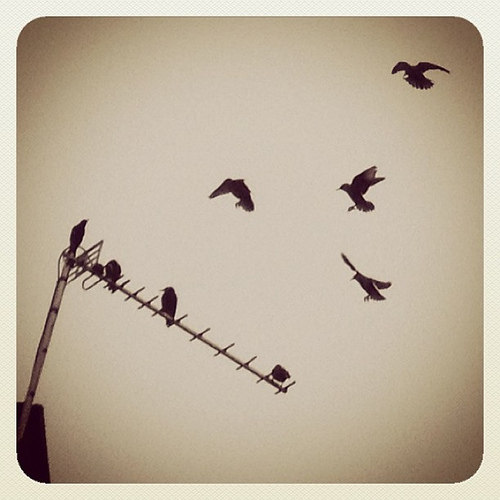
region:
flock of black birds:
[79, 47, 463, 407]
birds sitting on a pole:
[72, 203, 292, 360]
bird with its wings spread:
[323, 242, 405, 332]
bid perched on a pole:
[38, 200, 116, 261]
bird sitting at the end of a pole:
[261, 354, 327, 427]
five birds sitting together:
[56, 208, 308, 392]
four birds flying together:
[211, 52, 469, 303]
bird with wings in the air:
[327, 147, 396, 224]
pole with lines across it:
[61, 211, 319, 405]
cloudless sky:
[61, 67, 431, 446]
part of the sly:
[130, 123, 180, 188]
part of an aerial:
[212, 335, 244, 406]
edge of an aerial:
[271, 367, 293, 402]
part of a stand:
[17, 332, 64, 392]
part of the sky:
[366, 326, 427, 400]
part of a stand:
[23, 343, 63, 426]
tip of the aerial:
[283, 380, 298, 390]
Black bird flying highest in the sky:
[385, 55, 455, 90]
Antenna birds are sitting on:
[55, 245, 296, 400]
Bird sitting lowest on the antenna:
[265, 360, 290, 385]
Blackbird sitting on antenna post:
[61, 211, 91, 256]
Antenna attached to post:
[16, 242, 73, 457]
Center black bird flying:
[205, 172, 260, 212]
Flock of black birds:
[65, 55, 470, 385]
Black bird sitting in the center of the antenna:
[155, 275, 185, 330]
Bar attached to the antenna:
[185, 325, 210, 340]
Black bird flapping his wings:
[336, 160, 396, 218]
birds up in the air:
[29, 37, 450, 476]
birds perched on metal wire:
[64, 237, 304, 421]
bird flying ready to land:
[330, 160, 396, 224]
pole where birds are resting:
[22, 240, 70, 452]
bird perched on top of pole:
[61, 213, 94, 253]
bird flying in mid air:
[332, 250, 397, 314]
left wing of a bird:
[419, 51, 455, 77]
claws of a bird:
[359, 294, 374, 305]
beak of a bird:
[154, 285, 166, 293]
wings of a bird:
[351, 161, 395, 194]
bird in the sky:
[186, 148, 285, 233]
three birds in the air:
[213, 142, 424, 290]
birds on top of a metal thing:
[98, 259, 294, 359]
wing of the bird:
[379, 268, 399, 297]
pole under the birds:
[22, 306, 78, 367]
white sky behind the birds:
[329, 331, 403, 411]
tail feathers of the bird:
[398, 75, 434, 99]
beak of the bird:
[331, 183, 347, 197]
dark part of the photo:
[28, 27, 81, 97]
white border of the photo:
[1, 9, 28, 49]